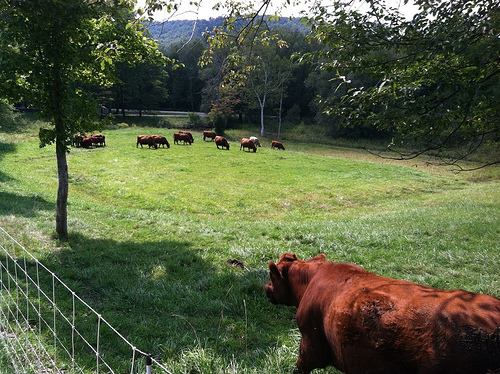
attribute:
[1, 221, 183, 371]
fence — short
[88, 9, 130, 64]
leaves — green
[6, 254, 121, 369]
fence — wire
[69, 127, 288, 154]
cows — standing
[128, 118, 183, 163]
cow — brown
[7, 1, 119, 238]
tree — short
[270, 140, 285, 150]
cow — grazing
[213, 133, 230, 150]
cow — grazing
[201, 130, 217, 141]
cow — grazing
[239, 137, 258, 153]
cow — grazing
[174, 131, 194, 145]
cow — grazing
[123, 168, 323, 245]
grass — green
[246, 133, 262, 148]
cow — pale colored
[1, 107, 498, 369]
grass — short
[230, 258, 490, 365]
cow — reddish brown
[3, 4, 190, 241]
tree — leafy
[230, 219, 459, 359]
cow — alone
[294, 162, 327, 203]
grass — lush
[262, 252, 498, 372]
cow — dirty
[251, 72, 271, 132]
trunk — white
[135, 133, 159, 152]
cow — grazing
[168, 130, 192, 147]
cow — grazing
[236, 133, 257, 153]
cow — grazing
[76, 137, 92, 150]
cow — grazing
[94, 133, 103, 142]
cow — standing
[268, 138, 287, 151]
cow — standing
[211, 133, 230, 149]
cow — standing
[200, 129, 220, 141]
cow — standing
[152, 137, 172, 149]
cow — standing